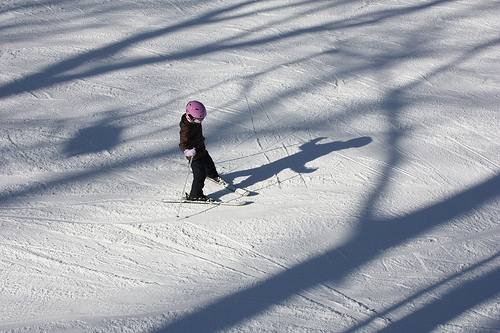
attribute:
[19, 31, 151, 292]
slope — snow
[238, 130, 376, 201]
shadow — dark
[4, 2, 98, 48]
shadow — dark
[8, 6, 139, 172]
slope — snowy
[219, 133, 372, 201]
shadow — dark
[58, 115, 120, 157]
shadow — dark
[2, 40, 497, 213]
shadow — dark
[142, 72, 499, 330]
shadow — dark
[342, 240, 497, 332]
shadow — dark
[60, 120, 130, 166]
shadow — dark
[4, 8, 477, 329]
slope — snowy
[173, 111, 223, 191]
clothes — warm